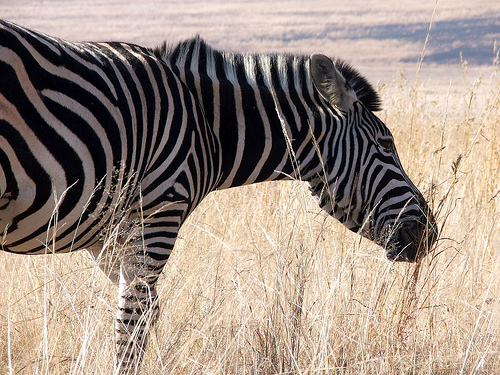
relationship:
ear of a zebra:
[311, 53, 347, 106] [0, 21, 435, 372]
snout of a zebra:
[388, 210, 437, 260] [0, 21, 435, 372]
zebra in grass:
[0, 21, 435, 372] [248, 79, 476, 371]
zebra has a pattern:
[0, 21, 435, 372] [20, 50, 212, 190]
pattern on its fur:
[20, 50, 212, 190] [112, 107, 291, 177]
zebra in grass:
[0, 21, 435, 372] [235, 182, 344, 372]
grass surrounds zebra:
[248, 79, 476, 371] [0, 21, 435, 372]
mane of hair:
[153, 32, 385, 113] [331, 56, 381, 108]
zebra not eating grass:
[0, 21, 435, 372] [0, 0, 500, 374]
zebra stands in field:
[0, 21, 435, 372] [0, 93, 498, 372]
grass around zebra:
[0, 0, 500, 374] [0, 21, 435, 372]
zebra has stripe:
[0, 21, 435, 372] [231, 53, 264, 183]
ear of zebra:
[311, 53, 347, 106] [0, 21, 435, 372]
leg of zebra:
[116, 203, 186, 373] [0, 21, 435, 372]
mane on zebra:
[159, 31, 383, 110] [0, 21, 435, 372]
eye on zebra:
[376, 134, 396, 150] [0, 21, 435, 372]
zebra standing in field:
[0, 21, 435, 372] [0, 93, 498, 372]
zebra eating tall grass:
[0, 21, 435, 372] [219, 189, 309, 372]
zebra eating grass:
[0, 21, 435, 372] [0, 0, 500, 374]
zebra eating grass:
[0, 21, 435, 372] [209, 62, 498, 345]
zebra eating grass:
[0, 21, 435, 372] [168, 60, 463, 373]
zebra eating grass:
[0, 21, 435, 372] [218, 81, 475, 372]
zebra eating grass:
[0, 21, 435, 372] [238, 50, 498, 373]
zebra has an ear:
[0, 21, 435, 372] [311, 38, 371, 137]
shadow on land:
[333, 0, 498, 84] [305, 0, 498, 160]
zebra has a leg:
[0, 21, 435, 372] [109, 193, 171, 373]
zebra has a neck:
[0, 21, 435, 372] [199, 30, 321, 209]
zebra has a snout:
[0, 21, 435, 372] [388, 215, 437, 260]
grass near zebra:
[0, 0, 500, 374] [0, 9, 456, 341]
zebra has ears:
[0, 21, 435, 372] [259, 20, 378, 150]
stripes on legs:
[86, 191, 198, 372] [101, 189, 193, 373]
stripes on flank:
[4, 54, 148, 256] [0, 33, 136, 251]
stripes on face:
[278, 111, 434, 206] [254, 17, 450, 284]